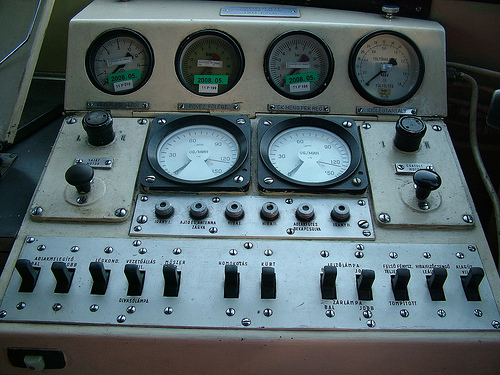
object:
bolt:
[91, 306, 96, 313]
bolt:
[117, 315, 124, 323]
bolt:
[226, 311, 232, 318]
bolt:
[326, 312, 332, 318]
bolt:
[401, 311, 407, 317]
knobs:
[393, 115, 429, 154]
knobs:
[409, 167, 446, 202]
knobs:
[82, 106, 119, 143]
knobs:
[63, 160, 95, 192]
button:
[10, 337, 67, 373]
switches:
[221, 261, 243, 303]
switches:
[258, 263, 279, 300]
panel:
[4, 240, 494, 322]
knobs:
[426, 262, 450, 295]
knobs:
[391, 263, 413, 293]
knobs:
[462, 260, 485, 302]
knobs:
[356, 263, 376, 295]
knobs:
[318, 262, 343, 298]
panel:
[220, 0, 303, 20]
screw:
[241, 317, 252, 326]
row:
[14, 257, 485, 302]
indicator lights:
[154, 200, 173, 220]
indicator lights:
[190, 201, 206, 217]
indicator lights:
[224, 201, 244, 219]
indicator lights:
[262, 202, 280, 219]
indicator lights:
[295, 202, 312, 222]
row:
[153, 199, 351, 223]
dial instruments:
[139, 117, 252, 194]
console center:
[0, 1, 500, 373]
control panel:
[0, 110, 499, 340]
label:
[218, 4, 301, 19]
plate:
[220, 7, 300, 17]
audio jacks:
[153, 200, 174, 220]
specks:
[215, 335, 295, 349]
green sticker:
[282, 72, 324, 87]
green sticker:
[192, 70, 229, 87]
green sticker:
[102, 68, 145, 86]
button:
[413, 168, 443, 213]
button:
[65, 159, 95, 204]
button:
[17, 354, 64, 371]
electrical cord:
[448, 59, 497, 247]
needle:
[360, 67, 386, 90]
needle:
[284, 52, 306, 86]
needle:
[105, 57, 125, 84]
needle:
[192, 51, 219, 86]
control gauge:
[82, 25, 154, 93]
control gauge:
[172, 27, 246, 99]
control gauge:
[262, 27, 333, 99]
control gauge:
[346, 30, 425, 104]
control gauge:
[260, 110, 360, 189]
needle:
[287, 146, 312, 174]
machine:
[6, 14, 498, 372]